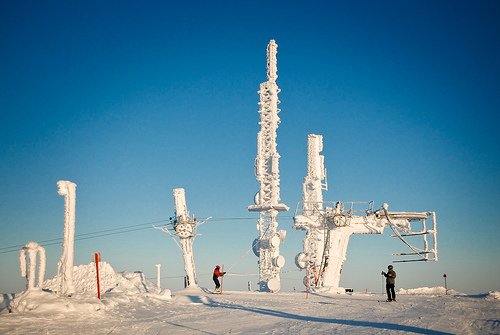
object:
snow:
[0, 39, 500, 335]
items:
[19, 39, 438, 296]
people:
[212, 265, 226, 292]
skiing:
[381, 265, 396, 302]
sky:
[0, 0, 500, 180]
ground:
[0, 290, 500, 335]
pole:
[95, 252, 101, 299]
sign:
[93, 252, 101, 262]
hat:
[216, 266, 220, 269]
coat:
[384, 269, 397, 284]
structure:
[152, 188, 213, 289]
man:
[381, 265, 396, 302]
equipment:
[292, 133, 438, 294]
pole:
[443, 273, 447, 295]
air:
[0, 0, 499, 291]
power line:
[0, 219, 171, 253]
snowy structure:
[247, 39, 290, 293]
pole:
[302, 133, 328, 212]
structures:
[247, 38, 438, 292]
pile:
[43, 261, 146, 294]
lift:
[374, 203, 439, 263]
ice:
[351, 214, 377, 232]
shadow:
[0, 313, 500, 335]